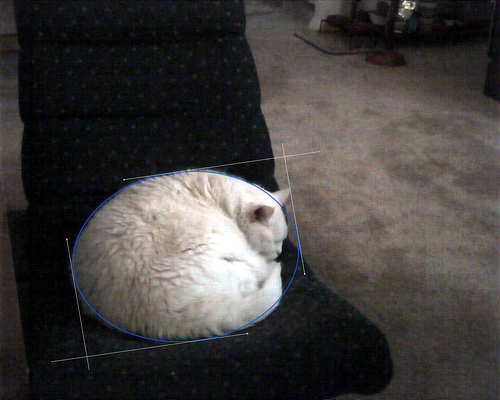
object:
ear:
[272, 189, 289, 205]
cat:
[71, 169, 290, 339]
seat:
[19, 232, 395, 400]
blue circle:
[71, 170, 290, 343]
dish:
[367, 52, 404, 67]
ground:
[254, 0, 500, 392]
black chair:
[14, 0, 395, 400]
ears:
[251, 188, 290, 223]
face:
[251, 219, 287, 261]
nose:
[276, 239, 284, 255]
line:
[65, 239, 92, 371]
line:
[51, 332, 251, 363]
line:
[281, 142, 307, 275]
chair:
[318, 0, 418, 69]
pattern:
[14, 0, 276, 204]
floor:
[0, 0, 500, 400]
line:
[123, 150, 321, 182]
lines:
[49, 142, 320, 371]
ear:
[249, 204, 275, 224]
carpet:
[0, 0, 497, 397]